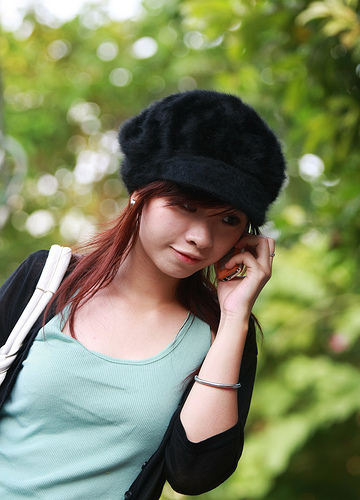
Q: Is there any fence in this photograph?
A: No, there are no fences.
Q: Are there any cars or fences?
A: No, there are no fences or cars.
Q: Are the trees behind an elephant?
A: No, the trees are behind the girl.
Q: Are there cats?
A: No, there are no cats.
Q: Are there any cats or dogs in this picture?
A: No, there are no cats or dogs.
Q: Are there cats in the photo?
A: No, there are no cats.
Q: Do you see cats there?
A: No, there are no cats.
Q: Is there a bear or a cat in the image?
A: No, there are no cats or bears.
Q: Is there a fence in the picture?
A: No, there are no fences.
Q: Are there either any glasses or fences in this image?
A: No, there are no fences or glasses.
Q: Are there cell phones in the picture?
A: Yes, there is a cell phone.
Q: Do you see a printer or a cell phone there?
A: Yes, there is a cell phone.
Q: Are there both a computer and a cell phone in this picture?
A: No, there is a cell phone but no computers.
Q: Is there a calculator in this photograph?
A: No, there are no calculators.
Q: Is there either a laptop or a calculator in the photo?
A: No, there are no calculators or laptops.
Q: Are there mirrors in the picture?
A: No, there are no mirrors.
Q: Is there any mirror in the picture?
A: No, there are no mirrors.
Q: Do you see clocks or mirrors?
A: No, there are no mirrors or clocks.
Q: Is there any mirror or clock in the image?
A: No, there are no mirrors or clocks.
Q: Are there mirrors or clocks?
A: No, there are no mirrors or clocks.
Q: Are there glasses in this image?
A: No, there are no glasses.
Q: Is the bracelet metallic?
A: Yes, the bracelet is metallic.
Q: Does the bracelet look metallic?
A: Yes, the bracelet is metallic.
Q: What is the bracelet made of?
A: The bracelet is made of metal.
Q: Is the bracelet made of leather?
A: No, the bracelet is made of metal.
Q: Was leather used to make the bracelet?
A: No, the bracelet is made of metal.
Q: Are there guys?
A: No, there are no guys.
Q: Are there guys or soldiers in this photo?
A: No, there are no guys or soldiers.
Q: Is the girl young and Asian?
A: Yes, the girl is young and asian.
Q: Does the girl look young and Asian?
A: Yes, the girl is young and asian.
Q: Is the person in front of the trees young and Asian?
A: Yes, the girl is young and asian.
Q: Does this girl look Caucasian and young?
A: No, the girl is young but asian.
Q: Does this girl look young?
A: Yes, the girl is young.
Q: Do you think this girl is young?
A: Yes, the girl is young.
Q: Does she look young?
A: Yes, the girl is young.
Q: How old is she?
A: The girl is young.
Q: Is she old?
A: No, the girl is young.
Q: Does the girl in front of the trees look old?
A: No, the girl is young.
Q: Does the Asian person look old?
A: No, the girl is young.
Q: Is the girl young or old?
A: The girl is young.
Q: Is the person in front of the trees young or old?
A: The girl is young.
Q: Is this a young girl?
A: Yes, this is a young girl.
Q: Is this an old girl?
A: No, this is a young girl.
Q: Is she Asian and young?
A: Yes, the girl is Asian and young.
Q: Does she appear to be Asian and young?
A: Yes, the girl is Asian and young.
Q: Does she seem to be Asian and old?
A: No, the girl is Asian but young.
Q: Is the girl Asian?
A: Yes, the girl is asian.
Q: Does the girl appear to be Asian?
A: Yes, the girl is asian.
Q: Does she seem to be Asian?
A: Yes, the girl is asian.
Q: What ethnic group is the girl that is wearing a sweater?
A: The girl is asian.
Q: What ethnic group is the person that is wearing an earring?
A: The girl is asian.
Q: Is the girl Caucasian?
A: No, the girl is asian.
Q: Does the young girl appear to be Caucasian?
A: No, the girl is asian.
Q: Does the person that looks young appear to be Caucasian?
A: No, the girl is asian.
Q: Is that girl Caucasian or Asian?
A: The girl is asian.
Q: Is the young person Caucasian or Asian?
A: The girl is asian.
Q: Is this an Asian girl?
A: Yes, this is an Asian girl.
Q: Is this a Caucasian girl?
A: No, this is an Asian girl.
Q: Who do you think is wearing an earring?
A: The girl is wearing an earring.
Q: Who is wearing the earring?
A: The girl is wearing an earring.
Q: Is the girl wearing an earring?
A: Yes, the girl is wearing an earring.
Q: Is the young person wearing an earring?
A: Yes, the girl is wearing an earring.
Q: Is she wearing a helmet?
A: No, the girl is wearing an earring.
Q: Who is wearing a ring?
A: The girl is wearing a ring.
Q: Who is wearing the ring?
A: The girl is wearing a ring.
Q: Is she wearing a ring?
A: Yes, the girl is wearing a ring.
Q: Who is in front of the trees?
A: The girl is in front of the trees.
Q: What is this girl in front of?
A: The girl is in front of the trees.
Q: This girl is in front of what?
A: The girl is in front of the trees.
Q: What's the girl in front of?
A: The girl is in front of the trees.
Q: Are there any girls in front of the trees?
A: Yes, there is a girl in front of the trees.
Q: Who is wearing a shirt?
A: The girl is wearing a shirt.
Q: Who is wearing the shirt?
A: The girl is wearing a shirt.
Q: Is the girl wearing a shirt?
A: Yes, the girl is wearing a shirt.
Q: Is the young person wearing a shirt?
A: Yes, the girl is wearing a shirt.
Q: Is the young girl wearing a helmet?
A: No, the girl is wearing a shirt.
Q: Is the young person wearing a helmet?
A: No, the girl is wearing a shirt.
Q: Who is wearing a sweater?
A: The girl is wearing a sweater.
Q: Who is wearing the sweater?
A: The girl is wearing a sweater.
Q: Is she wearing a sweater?
A: Yes, the girl is wearing a sweater.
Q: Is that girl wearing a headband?
A: No, the girl is wearing a sweater.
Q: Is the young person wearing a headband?
A: No, the girl is wearing a sweater.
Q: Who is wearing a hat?
A: The girl is wearing a hat.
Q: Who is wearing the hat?
A: The girl is wearing a hat.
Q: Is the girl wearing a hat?
A: Yes, the girl is wearing a hat.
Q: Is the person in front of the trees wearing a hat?
A: Yes, the girl is wearing a hat.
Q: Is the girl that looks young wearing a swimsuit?
A: No, the girl is wearing a hat.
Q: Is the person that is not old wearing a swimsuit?
A: No, the girl is wearing a hat.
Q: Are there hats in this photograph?
A: Yes, there is a hat.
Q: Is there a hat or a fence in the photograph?
A: Yes, there is a hat.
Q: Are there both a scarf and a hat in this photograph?
A: No, there is a hat but no scarves.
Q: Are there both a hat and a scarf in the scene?
A: No, there is a hat but no scarves.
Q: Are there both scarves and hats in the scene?
A: No, there is a hat but no scarves.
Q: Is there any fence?
A: No, there are no fences.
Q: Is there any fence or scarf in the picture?
A: No, there are no fences or scarves.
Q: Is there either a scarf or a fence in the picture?
A: No, there are no fences or scarves.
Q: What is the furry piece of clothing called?
A: The clothing item is a hat.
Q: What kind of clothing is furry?
A: The clothing is a hat.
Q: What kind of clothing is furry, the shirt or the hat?
A: The hat is furry.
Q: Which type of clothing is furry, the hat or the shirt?
A: The hat is furry.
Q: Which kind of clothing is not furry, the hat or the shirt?
A: The shirt is not furry.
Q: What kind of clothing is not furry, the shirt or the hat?
A: The shirt is not furry.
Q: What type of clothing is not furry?
A: The clothing is a shirt.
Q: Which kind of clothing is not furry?
A: The clothing is a shirt.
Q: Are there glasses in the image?
A: No, there are no glasses.